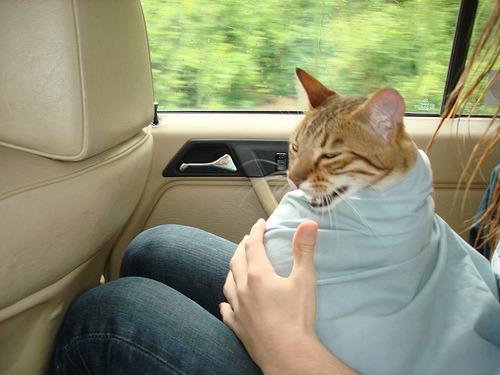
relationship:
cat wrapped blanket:
[264, 62, 459, 281] [245, 146, 498, 370]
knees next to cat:
[90, 216, 189, 311] [264, 62, 459, 281]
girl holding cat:
[42, 96, 498, 373] [264, 62, 459, 281]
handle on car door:
[178, 150, 239, 170] [135, 2, 498, 293]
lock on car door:
[145, 93, 163, 133] [135, 2, 482, 212]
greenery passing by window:
[139, 2, 499, 128] [137, 0, 498, 115]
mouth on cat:
[295, 183, 349, 210] [264, 62, 459, 281]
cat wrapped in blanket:
[264, 62, 496, 372] [245, 146, 498, 370]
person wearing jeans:
[54, 2, 493, 371] [43, 216, 293, 371]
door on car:
[104, 1, 498, 302] [0, 2, 500, 371]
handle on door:
[178, 150, 239, 170] [104, 1, 498, 302]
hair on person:
[410, 4, 498, 262] [54, 2, 493, 371]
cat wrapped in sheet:
[264, 62, 459, 281] [238, 146, 498, 373]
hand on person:
[216, 212, 318, 372] [45, 100, 492, 375]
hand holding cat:
[216, 212, 318, 372] [264, 62, 459, 281]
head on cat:
[279, 60, 427, 224] [264, 62, 459, 281]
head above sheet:
[279, 60, 427, 224] [238, 146, 498, 373]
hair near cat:
[410, 4, 498, 262] [264, 62, 496, 372]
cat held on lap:
[264, 62, 459, 281] [60, 206, 447, 373]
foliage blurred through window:
[142, 4, 498, 113] [137, 0, 498, 115]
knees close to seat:
[90, 216, 189, 311] [2, 0, 158, 371]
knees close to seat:
[107, 216, 187, 287] [2, 0, 158, 371]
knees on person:
[90, 216, 189, 311] [54, 2, 493, 371]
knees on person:
[107, 216, 187, 287] [54, 2, 493, 371]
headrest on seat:
[1, 0, 157, 161] [2, 128, 156, 373]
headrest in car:
[1, 0, 157, 161] [0, 2, 500, 371]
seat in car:
[2, 128, 156, 373] [0, 2, 500, 371]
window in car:
[137, 0, 498, 115] [0, 2, 500, 371]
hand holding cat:
[216, 212, 318, 372] [264, 62, 496, 372]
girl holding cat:
[42, 0, 497, 373] [264, 62, 496, 372]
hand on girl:
[216, 212, 318, 372] [42, 0, 497, 373]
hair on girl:
[410, 4, 498, 262] [42, 0, 497, 373]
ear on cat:
[363, 85, 404, 145] [264, 62, 496, 372]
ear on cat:
[292, 65, 338, 108] [264, 62, 496, 372]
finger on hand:
[243, 216, 275, 278] [216, 212, 318, 372]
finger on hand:
[219, 265, 246, 313] [216, 212, 318, 372]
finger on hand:
[215, 298, 236, 329] [216, 212, 318, 372]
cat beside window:
[264, 62, 496, 372] [137, 0, 498, 115]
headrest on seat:
[1, 0, 157, 161] [2, 0, 158, 371]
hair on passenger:
[410, 4, 498, 262] [45, 0, 498, 375]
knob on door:
[149, 96, 162, 126] [104, 1, 498, 302]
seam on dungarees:
[50, 322, 190, 372] [42, 223, 262, 370]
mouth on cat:
[295, 183, 349, 210] [264, 62, 496, 372]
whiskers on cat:
[237, 153, 367, 248] [264, 62, 496, 372]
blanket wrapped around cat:
[245, 146, 498, 370] [264, 62, 496, 372]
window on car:
[137, 0, 498, 115] [0, 2, 500, 371]